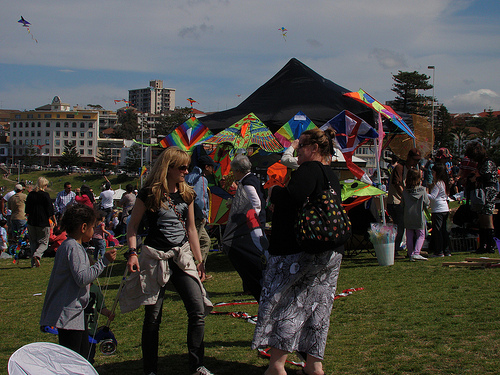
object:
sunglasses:
[177, 165, 189, 172]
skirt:
[251, 251, 343, 360]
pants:
[141, 259, 206, 374]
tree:
[266, 0, 299, 349]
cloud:
[448, 84, 500, 111]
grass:
[0, 171, 499, 375]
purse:
[294, 160, 352, 244]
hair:
[143, 146, 196, 213]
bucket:
[372, 242, 395, 266]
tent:
[196, 57, 415, 137]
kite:
[17, 15, 37, 43]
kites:
[194, 112, 285, 161]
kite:
[6, 342, 98, 375]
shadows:
[74, 172, 112, 182]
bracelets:
[123, 247, 138, 260]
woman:
[116, 146, 215, 374]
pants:
[406, 211, 425, 257]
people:
[0, 125, 499, 374]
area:
[0, 0, 499, 375]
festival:
[0, 57, 499, 374]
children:
[400, 168, 430, 262]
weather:
[0, 0, 500, 114]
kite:
[277, 25, 287, 42]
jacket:
[118, 241, 214, 319]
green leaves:
[406, 87, 439, 116]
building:
[0, 80, 217, 173]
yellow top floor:
[8, 111, 99, 121]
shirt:
[39, 238, 110, 330]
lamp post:
[427, 66, 435, 159]